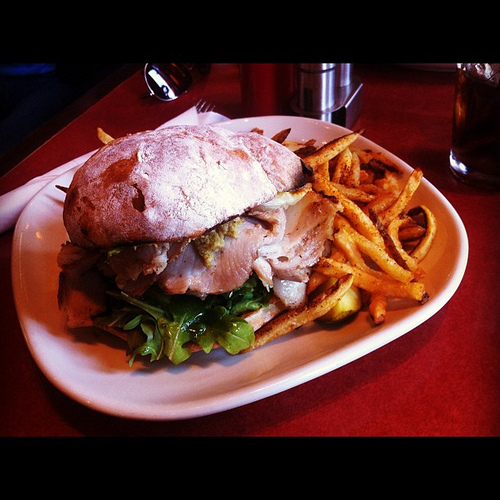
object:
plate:
[10, 111, 470, 425]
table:
[1, 64, 500, 435]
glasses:
[143, 63, 211, 103]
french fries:
[246, 128, 436, 354]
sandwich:
[56, 124, 338, 370]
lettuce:
[93, 279, 273, 367]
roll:
[63, 126, 303, 245]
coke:
[447, 70, 500, 187]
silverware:
[0, 102, 230, 237]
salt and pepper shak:
[285, 61, 363, 131]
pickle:
[309, 277, 361, 324]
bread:
[63, 124, 311, 248]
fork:
[195, 97, 216, 114]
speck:
[321, 304, 324, 308]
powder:
[162, 158, 228, 209]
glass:
[448, 61, 500, 191]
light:
[449, 149, 468, 174]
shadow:
[0, 436, 500, 500]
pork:
[55, 185, 338, 327]